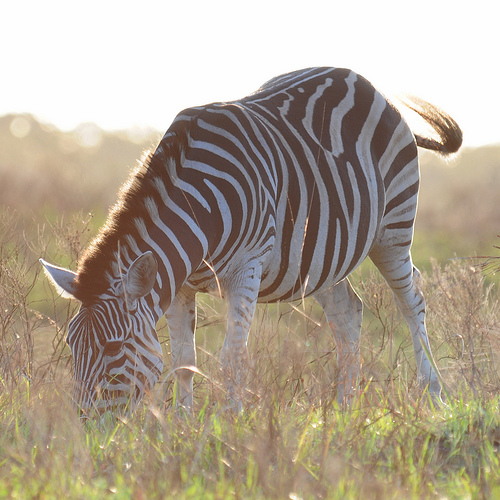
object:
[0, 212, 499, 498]
field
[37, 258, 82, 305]
ear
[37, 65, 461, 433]
zebra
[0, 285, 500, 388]
floor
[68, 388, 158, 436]
mouth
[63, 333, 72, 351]
eyes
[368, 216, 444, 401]
leg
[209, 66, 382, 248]
stripes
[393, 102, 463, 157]
tail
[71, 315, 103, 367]
forehead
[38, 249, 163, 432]
head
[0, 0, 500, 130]
bright sky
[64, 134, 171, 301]
mane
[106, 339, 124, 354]
eye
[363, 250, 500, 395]
stems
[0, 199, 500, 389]
weeds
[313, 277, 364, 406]
leg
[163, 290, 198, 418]
leg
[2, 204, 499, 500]
forest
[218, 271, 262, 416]
legs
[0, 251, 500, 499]
grass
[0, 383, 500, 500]
yellow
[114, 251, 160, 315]
ear